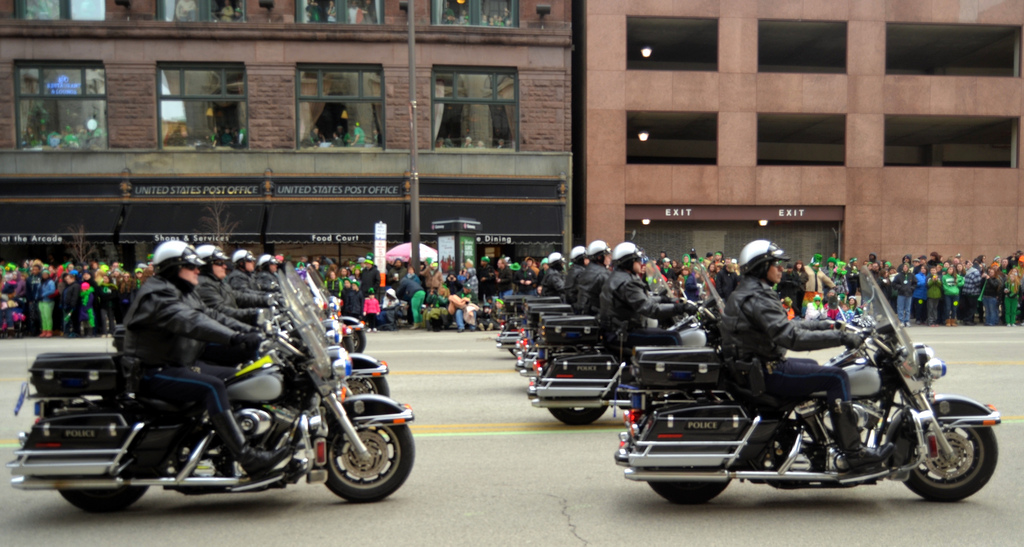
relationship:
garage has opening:
[589, 0, 1022, 279] [620, 13, 726, 80]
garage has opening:
[589, 0, 1022, 279] [750, 11, 855, 76]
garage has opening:
[589, 0, 1022, 279] [879, 17, 1022, 81]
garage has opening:
[589, 0, 1022, 279] [618, 105, 724, 167]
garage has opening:
[589, 0, 1022, 279] [750, 103, 858, 170]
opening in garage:
[750, 16, 859, 79] [589, 8, 1020, 268]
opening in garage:
[878, 20, 993, 83] [583, 8, 1020, 344]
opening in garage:
[755, 108, 849, 166] [589, 0, 1022, 279]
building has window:
[13, 0, 573, 263] [430, 64, 519, 148]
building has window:
[13, 0, 573, 263] [296, 60, 385, 150]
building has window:
[13, 0, 573, 263] [155, 63, 247, 146]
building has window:
[13, 0, 573, 263] [18, 63, 105, 149]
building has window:
[13, 0, 573, 263] [433, 0, 519, 29]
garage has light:
[589, 0, 1022, 279] [631, 122, 657, 149]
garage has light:
[589, 0, 1022, 279] [627, 38, 658, 65]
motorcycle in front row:
[610, 267, 1002, 508] [492, 235, 1001, 514]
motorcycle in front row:
[531, 310, 637, 431] [492, 235, 1001, 514]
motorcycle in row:
[14, 272, 423, 516] [10, 257, 412, 510]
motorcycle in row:
[303, 272, 364, 350] [10, 257, 412, 510]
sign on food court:
[122, 178, 262, 208] [3, 172, 546, 293]